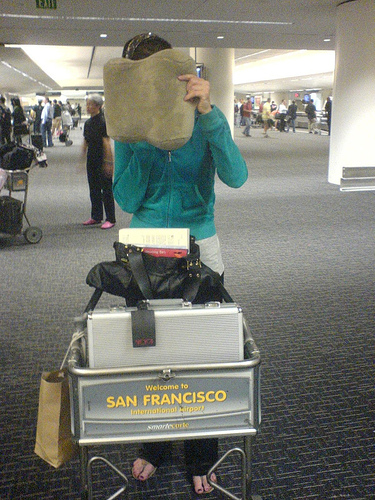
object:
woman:
[101, 29, 251, 495]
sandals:
[190, 454, 228, 495]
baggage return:
[309, 117, 322, 135]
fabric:
[111, 102, 248, 242]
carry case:
[88, 302, 242, 369]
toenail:
[197, 487, 202, 492]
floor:
[293, 179, 324, 211]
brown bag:
[29, 363, 76, 471]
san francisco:
[101, 389, 227, 409]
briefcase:
[85, 297, 245, 367]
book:
[114, 226, 193, 259]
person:
[77, 95, 114, 233]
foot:
[130, 442, 167, 480]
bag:
[85, 227, 234, 317]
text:
[130, 405, 206, 431]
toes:
[138, 471, 142, 479]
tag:
[131, 309, 156, 348]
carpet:
[0, 122, 375, 500]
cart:
[0, 139, 44, 244]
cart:
[69, 227, 262, 497]